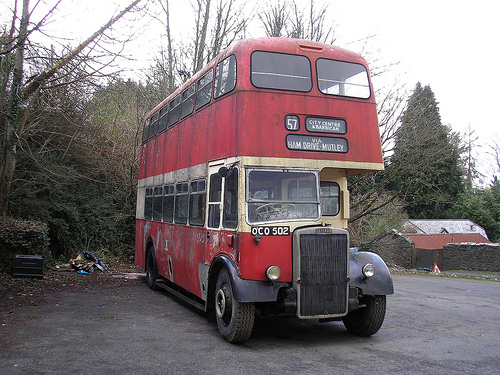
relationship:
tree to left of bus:
[373, 76, 467, 217] [132, 30, 397, 338]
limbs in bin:
[5, 219, 43, 246] [8, 216, 52, 286]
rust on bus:
[154, 215, 204, 250] [121, 38, 411, 348]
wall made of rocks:
[405, 235, 498, 265] [454, 246, 478, 266]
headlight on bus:
[263, 261, 280, 277] [132, 30, 397, 338]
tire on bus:
[215, 269, 257, 344] [132, 30, 397, 338]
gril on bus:
[297, 229, 347, 319] [121, 38, 411, 348]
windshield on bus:
[253, 166, 345, 228] [121, 38, 411, 348]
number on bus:
[283, 111, 303, 130] [96, 30, 397, 343]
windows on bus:
[143, 171, 213, 225] [121, 38, 411, 348]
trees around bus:
[32, 63, 143, 269] [121, 38, 411, 348]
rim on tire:
[214, 280, 236, 323] [209, 257, 266, 344]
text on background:
[275, 106, 355, 156] [282, 100, 353, 152]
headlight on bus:
[265, 265, 281, 280] [140, 27, 402, 355]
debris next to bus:
[57, 240, 117, 282] [121, 38, 411, 348]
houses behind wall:
[398, 205, 496, 281] [370, 234, 498, 285]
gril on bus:
[300, 233, 348, 317] [132, 30, 397, 338]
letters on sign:
[286, 138, 347, 153] [281, 130, 351, 147]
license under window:
[248, 225, 296, 245] [249, 177, 344, 215]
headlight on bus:
[265, 265, 281, 280] [117, 30, 387, 328]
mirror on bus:
[219, 167, 230, 178] [88, 29, 402, 322]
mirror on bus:
[195, 164, 243, 176] [67, 10, 417, 333]